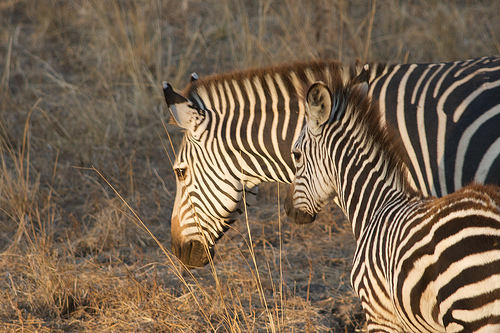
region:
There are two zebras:
[139, 37, 398, 290]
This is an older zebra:
[135, 56, 281, 281]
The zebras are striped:
[112, 40, 497, 330]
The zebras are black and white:
[154, 55, 494, 332]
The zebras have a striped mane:
[144, 47, 449, 205]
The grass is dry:
[0, 4, 361, 324]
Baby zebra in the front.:
[270, 67, 498, 329]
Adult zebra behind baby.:
[157, 51, 499, 294]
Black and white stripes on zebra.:
[277, 71, 498, 331]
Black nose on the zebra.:
[274, 182, 314, 230]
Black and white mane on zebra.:
[161, 57, 361, 139]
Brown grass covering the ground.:
[2, 3, 494, 330]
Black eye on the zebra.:
[169, 159, 192, 181]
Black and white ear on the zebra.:
[153, 70, 200, 135]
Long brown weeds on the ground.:
[96, 149, 304, 331]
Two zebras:
[141, 53, 498, 311]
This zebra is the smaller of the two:
[283, 85, 495, 323]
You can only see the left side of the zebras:
[141, 76, 478, 328]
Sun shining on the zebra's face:
[161, 193, 237, 268]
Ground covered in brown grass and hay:
[18, 35, 168, 324]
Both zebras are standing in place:
[155, 80, 483, 323]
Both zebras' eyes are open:
[162, 136, 312, 187]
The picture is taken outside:
[21, 30, 481, 314]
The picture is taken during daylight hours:
[18, 12, 492, 324]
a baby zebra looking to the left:
[285, 75, 498, 331]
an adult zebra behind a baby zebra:
[162, 56, 496, 329]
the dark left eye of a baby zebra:
[294, 147, 303, 160]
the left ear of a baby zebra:
[301, 77, 331, 129]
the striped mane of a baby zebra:
[329, 84, 411, 197]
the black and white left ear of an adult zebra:
[160, 82, 196, 130]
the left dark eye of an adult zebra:
[174, 164, 187, 180]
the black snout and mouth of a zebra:
[170, 231, 209, 266]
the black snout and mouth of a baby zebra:
[281, 190, 315, 225]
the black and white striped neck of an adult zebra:
[221, 104, 312, 191]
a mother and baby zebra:
[155, 33, 498, 325]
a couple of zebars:
[143, 46, 498, 331]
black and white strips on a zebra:
[384, 226, 478, 318]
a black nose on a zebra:
[170, 235, 212, 267]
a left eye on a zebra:
[176, 162, 189, 181]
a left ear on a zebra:
[157, 80, 204, 135]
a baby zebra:
[285, 76, 499, 330]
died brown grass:
[0, 81, 95, 331]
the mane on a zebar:
[217, 68, 288, 107]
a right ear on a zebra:
[347, 58, 376, 95]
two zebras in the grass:
[135, 37, 496, 332]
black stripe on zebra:
[195, 162, 235, 204]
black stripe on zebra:
[178, 189, 218, 221]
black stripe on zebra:
[186, 210, 215, 230]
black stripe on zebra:
[184, 226, 214, 246]